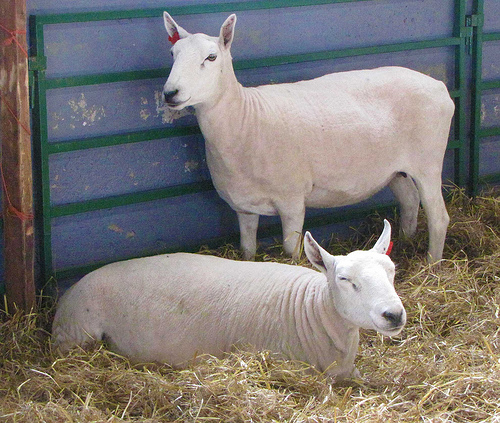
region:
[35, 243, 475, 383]
sheep laying in hay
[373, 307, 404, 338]
black nose of sheep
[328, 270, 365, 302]
left eye of sheep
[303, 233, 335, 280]
left ear of sheep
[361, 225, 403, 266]
right ear of sheep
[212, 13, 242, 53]
left ear of sheep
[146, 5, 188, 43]
left ear of sheep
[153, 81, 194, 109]
black nose of sheep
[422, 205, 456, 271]
back leg of sheep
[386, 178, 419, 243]
back leg of sheep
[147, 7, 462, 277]
a sheep standing up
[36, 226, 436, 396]
sheep laying down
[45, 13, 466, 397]
two sheep in the hay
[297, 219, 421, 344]
sheep with it's eye's closed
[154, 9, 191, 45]
red tag in the sheeps ear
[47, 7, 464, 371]
two recently sheered sheep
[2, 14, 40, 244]
red twine tied around a pole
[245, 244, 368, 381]
wrinkles in the sheeps skin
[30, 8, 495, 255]
a green metal gate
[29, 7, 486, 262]
a wall painted blue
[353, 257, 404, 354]
Animal has white face.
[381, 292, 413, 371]
Animal has black nose.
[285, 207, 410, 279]
Animal has white ears.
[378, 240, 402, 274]
Red tag on animal's ear.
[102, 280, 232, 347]
Animal has white back.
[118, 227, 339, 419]
Animal is laying in hay.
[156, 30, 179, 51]
Red tag on animal's ear.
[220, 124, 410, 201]
Animal has white fur.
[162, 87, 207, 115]
Animal has black nose.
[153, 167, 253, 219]
Animal is standing near green fence.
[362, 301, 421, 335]
Animal has black nose.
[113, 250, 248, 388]
Animal has white back.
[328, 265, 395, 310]
Animal's eyes are shut.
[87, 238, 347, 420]
Animal is laying down in hay.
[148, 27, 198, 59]
Red tag on animal's ear.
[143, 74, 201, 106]
Animal has black nose.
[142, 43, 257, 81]
Animal has light eyes.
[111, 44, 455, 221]
Animal is standing near green fence.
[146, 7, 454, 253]
a standing white sheep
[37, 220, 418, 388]
a resting white sheep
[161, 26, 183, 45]
a red ear tag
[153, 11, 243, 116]
a white sheep's face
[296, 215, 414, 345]
a white sheep's face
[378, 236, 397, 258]
a red ear tag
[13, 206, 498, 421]
a brown hay covered floor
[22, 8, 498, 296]
a metal green fence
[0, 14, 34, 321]
a wooden support pole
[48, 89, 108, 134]
a paint scratched wall